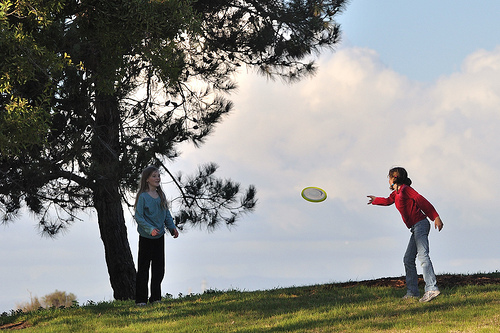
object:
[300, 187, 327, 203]
frisbee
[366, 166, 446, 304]
girl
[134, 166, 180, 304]
girl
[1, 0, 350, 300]
tree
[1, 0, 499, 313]
sky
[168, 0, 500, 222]
cloud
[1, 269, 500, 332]
grass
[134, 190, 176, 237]
shirt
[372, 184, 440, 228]
shirt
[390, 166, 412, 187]
hair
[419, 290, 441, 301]
shoe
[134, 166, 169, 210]
hair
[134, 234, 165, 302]
pants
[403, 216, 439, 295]
pants